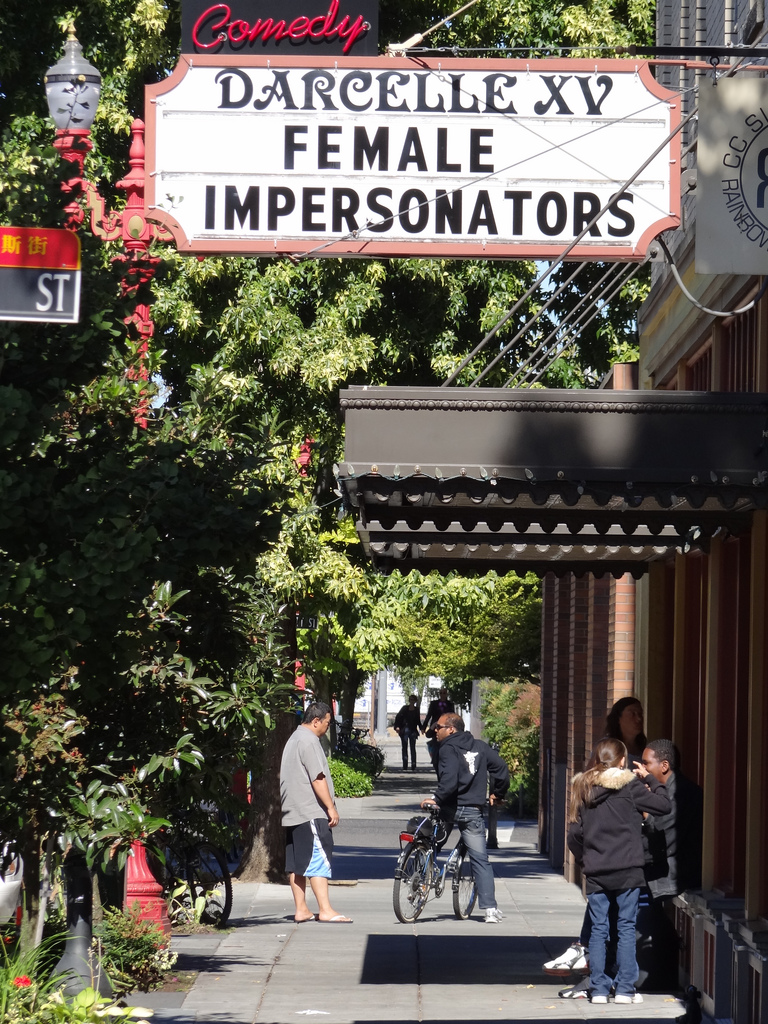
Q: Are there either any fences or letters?
A: Yes, there are letters.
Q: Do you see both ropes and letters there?
A: No, there are letters but no ropes.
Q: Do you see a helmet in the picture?
A: No, there are no helmets.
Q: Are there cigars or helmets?
A: No, there are no helmets or cigars.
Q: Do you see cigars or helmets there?
A: No, there are no helmets or cigars.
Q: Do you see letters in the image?
A: Yes, there are letters.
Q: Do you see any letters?
A: Yes, there are letters.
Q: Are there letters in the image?
A: Yes, there are letters.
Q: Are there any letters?
A: Yes, there are letters.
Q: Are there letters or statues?
A: Yes, there are letters.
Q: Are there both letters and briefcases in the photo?
A: No, there are letters but no briefcases.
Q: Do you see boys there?
A: No, there are no boys.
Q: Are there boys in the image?
A: No, there are no boys.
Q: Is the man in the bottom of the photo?
A: Yes, the man is in the bottom of the image.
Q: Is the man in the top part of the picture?
A: No, the man is in the bottom of the image.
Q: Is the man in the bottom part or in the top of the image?
A: The man is in the bottom of the image.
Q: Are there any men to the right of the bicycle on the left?
A: Yes, there is a man to the right of the bicycle.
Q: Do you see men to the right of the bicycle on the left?
A: Yes, there is a man to the right of the bicycle.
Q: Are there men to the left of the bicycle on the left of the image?
A: No, the man is to the right of the bicycle.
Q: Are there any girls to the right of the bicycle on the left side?
A: No, there is a man to the right of the bicycle.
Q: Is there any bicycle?
A: Yes, there is a bicycle.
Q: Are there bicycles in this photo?
A: Yes, there is a bicycle.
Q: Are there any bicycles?
A: Yes, there is a bicycle.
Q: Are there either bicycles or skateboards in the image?
A: Yes, there is a bicycle.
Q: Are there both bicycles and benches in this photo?
A: No, there is a bicycle but no benches.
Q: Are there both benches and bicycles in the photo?
A: No, there is a bicycle but no benches.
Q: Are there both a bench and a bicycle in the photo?
A: No, there is a bicycle but no benches.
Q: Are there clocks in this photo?
A: No, there are no clocks.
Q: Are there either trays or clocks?
A: No, there are no clocks or trays.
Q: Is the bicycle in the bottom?
A: Yes, the bicycle is in the bottom of the image.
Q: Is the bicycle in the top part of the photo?
A: No, the bicycle is in the bottom of the image.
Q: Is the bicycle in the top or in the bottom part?
A: The bicycle is in the bottom of the image.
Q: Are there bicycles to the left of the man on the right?
A: Yes, there is a bicycle to the left of the man.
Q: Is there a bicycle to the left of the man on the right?
A: Yes, there is a bicycle to the left of the man.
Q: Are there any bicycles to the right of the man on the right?
A: No, the bicycle is to the left of the man.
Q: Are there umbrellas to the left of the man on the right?
A: No, there is a bicycle to the left of the man.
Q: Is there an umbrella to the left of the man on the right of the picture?
A: No, there is a bicycle to the left of the man.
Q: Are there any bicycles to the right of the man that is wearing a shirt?
A: Yes, there is a bicycle to the right of the man.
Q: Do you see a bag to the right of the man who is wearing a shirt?
A: No, there is a bicycle to the right of the man.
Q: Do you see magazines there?
A: No, there are no magazines.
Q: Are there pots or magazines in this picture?
A: No, there are no magazines or pots.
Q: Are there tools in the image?
A: No, there are no tools.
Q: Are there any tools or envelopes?
A: No, there are no tools or envelopes.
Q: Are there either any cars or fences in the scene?
A: No, there are no cars or fences.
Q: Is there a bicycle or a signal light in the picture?
A: Yes, there is a bicycle.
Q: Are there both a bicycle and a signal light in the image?
A: No, there is a bicycle but no traffic lights.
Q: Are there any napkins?
A: No, there are no napkins.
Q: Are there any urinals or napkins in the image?
A: No, there are no napkins or urinals.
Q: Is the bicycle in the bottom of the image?
A: Yes, the bicycle is in the bottom of the image.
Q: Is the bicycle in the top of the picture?
A: No, the bicycle is in the bottom of the image.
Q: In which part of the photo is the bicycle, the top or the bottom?
A: The bicycle is in the bottom of the image.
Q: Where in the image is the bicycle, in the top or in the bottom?
A: The bicycle is in the bottom of the image.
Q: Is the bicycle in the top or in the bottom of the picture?
A: The bicycle is in the bottom of the image.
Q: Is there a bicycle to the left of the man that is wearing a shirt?
A: Yes, there is a bicycle to the left of the man.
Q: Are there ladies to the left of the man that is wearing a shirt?
A: No, there is a bicycle to the left of the man.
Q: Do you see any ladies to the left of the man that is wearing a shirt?
A: No, there is a bicycle to the left of the man.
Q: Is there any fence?
A: No, there are no fences.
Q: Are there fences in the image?
A: No, there are no fences.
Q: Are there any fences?
A: No, there are no fences.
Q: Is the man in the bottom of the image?
A: Yes, the man is in the bottom of the image.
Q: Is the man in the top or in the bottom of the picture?
A: The man is in the bottom of the image.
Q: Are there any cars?
A: No, there are no cars.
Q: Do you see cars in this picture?
A: No, there are no cars.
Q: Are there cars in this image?
A: No, there are no cars.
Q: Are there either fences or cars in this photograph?
A: No, there are no cars or fences.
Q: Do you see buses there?
A: No, there are no buses.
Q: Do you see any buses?
A: No, there are no buses.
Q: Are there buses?
A: No, there are no buses.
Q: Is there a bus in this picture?
A: No, there are no buses.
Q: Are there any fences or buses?
A: No, there are no buses or fences.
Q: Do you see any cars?
A: No, there are no cars.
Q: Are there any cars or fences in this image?
A: No, there are no cars or fences.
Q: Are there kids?
A: No, there are no kids.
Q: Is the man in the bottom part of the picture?
A: Yes, the man is in the bottom of the image.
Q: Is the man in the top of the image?
A: No, the man is in the bottom of the image.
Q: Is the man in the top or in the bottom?
A: The man is in the bottom of the image.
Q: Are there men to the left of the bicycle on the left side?
A: No, the man is to the right of the bicycle.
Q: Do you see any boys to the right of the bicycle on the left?
A: No, there is a man to the right of the bicycle.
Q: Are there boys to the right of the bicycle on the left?
A: No, there is a man to the right of the bicycle.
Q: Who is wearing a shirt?
A: The man is wearing a shirt.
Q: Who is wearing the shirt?
A: The man is wearing a shirt.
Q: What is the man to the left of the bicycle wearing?
A: The man is wearing a shirt.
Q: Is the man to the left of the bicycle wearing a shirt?
A: Yes, the man is wearing a shirt.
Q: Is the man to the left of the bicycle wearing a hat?
A: No, the man is wearing a shirt.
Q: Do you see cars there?
A: No, there are no cars.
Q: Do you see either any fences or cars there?
A: No, there are no cars or fences.